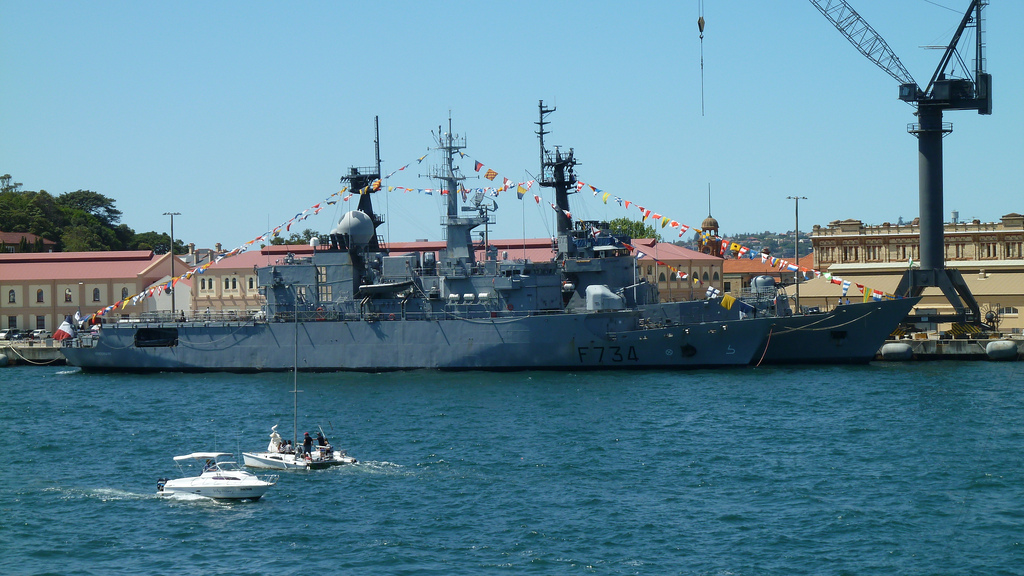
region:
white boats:
[143, 423, 356, 531]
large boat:
[67, 142, 889, 399]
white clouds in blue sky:
[710, 72, 800, 165]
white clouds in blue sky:
[664, 40, 754, 101]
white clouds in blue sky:
[444, 34, 520, 95]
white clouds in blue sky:
[292, 48, 362, 100]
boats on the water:
[155, 410, 355, 519]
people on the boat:
[257, 413, 337, 467]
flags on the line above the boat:
[469, 154, 549, 218]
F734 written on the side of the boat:
[571, 332, 647, 370]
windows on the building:
[8, 279, 132, 305]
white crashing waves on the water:
[99, 487, 144, 507]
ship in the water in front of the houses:
[55, 78, 928, 380]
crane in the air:
[829, 6, 919, 93]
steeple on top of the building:
[702, 209, 718, 230]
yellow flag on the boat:
[724, 281, 738, 310]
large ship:
[101, 164, 890, 384]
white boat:
[169, 463, 281, 509]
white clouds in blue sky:
[433, 74, 465, 94]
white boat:
[149, 443, 277, 539]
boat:
[251, 414, 341, 487]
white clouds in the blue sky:
[49, 54, 130, 121]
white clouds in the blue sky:
[190, 43, 268, 98]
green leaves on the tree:
[59, 204, 86, 225]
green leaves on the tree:
[11, 183, 122, 256]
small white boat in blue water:
[142, 450, 269, 511]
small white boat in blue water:
[244, 402, 344, 475]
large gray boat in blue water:
[18, 126, 905, 374]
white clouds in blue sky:
[214, 58, 271, 116]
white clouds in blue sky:
[752, 114, 807, 159]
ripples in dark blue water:
[559, 423, 646, 455]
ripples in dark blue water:
[710, 466, 790, 521]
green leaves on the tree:
[122, 209, 157, 249]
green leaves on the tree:
[99, 180, 134, 229]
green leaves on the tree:
[78, 203, 136, 267]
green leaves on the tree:
[23, 189, 49, 238]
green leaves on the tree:
[14, 177, 54, 238]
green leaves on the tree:
[52, 189, 110, 244]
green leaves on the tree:
[43, 127, 124, 205]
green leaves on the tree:
[111, 221, 181, 261]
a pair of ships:
[31, 48, 948, 416]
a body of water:
[29, 328, 1019, 573]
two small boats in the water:
[123, 376, 379, 538]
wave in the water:
[69, 470, 164, 522]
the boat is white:
[146, 432, 284, 538]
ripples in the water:
[396, 369, 978, 573]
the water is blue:
[12, 357, 1022, 561]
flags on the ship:
[82, 135, 876, 352]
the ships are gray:
[63, 111, 885, 372]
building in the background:
[7, 218, 197, 333]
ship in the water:
[75, 117, 902, 413]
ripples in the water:
[509, 399, 751, 536]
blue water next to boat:
[536, 386, 780, 494]